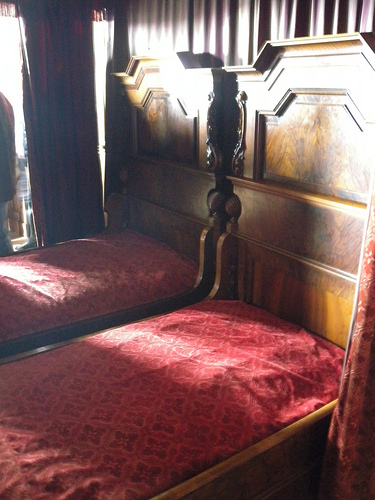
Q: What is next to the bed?
A: Rail of bed.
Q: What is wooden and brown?
A: The headboard.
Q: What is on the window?
A: A dark curtain.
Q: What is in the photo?
A: Two beds.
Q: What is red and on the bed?
A: The sheet.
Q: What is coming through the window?
A: Light.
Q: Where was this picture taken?
A: A bedroom.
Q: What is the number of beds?
A: Two.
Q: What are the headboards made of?
A: Dark wood.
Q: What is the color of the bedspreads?
A: Red.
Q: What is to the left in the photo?
A: A window with curtains.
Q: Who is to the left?
A: A man looking out the window.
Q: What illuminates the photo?
A: Natural sunlight.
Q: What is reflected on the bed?
A: Sunlight.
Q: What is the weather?
A: Sunny.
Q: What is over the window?
A: Curtains.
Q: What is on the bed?
A: A red bedspread.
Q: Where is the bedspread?
A: On the bed.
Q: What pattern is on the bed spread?
A: Diamonds.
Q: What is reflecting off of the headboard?
A: Sunlight.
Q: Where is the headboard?
A: At the front of each bed.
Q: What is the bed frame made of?
A: Wood.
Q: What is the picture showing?
A: Two beds.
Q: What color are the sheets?
A: Red.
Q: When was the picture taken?
A: During the day.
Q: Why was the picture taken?
A: To capture the two beds.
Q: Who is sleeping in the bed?
A: No one.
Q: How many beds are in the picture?
A: Two.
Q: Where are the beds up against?
A: A wall.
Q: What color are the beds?
A: Brown.